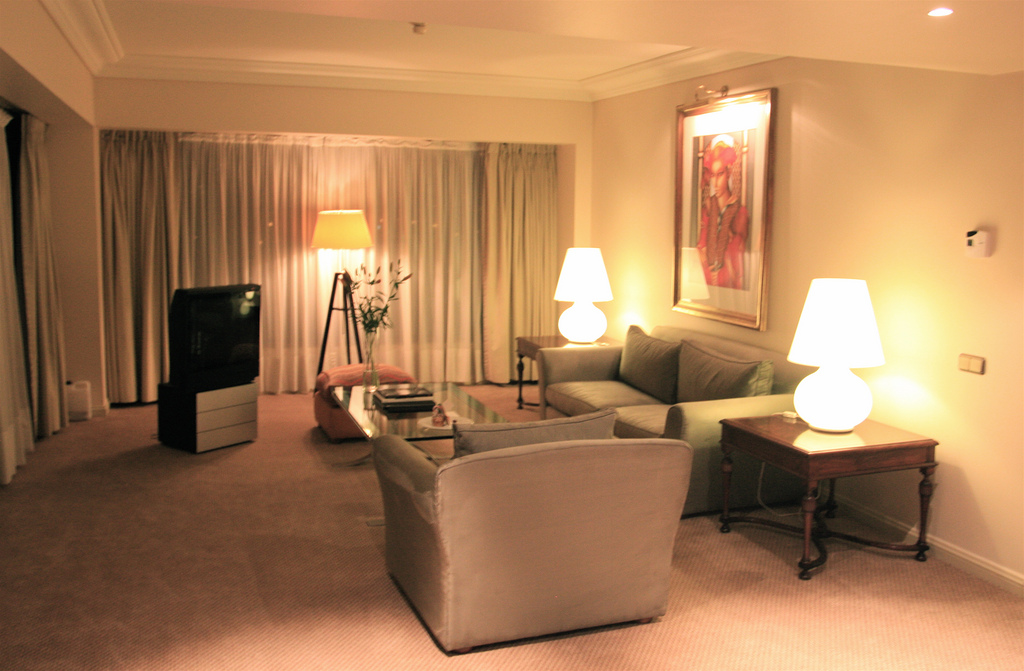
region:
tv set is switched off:
[173, 283, 268, 398]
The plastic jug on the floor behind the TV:
[54, 369, 100, 430]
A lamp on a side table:
[770, 246, 951, 597]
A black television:
[134, 234, 311, 421]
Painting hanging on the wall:
[622, 82, 820, 349]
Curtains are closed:
[78, 107, 610, 415]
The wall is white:
[809, 131, 912, 255]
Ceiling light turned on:
[916, 2, 978, 42]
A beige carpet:
[93, 507, 297, 627]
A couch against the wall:
[538, 322, 803, 511]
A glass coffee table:
[318, 359, 511, 458]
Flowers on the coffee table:
[302, 219, 428, 423]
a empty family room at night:
[78, 62, 946, 632]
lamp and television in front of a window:
[98, 122, 368, 449]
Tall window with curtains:
[280, 137, 553, 381]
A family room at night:
[67, 74, 962, 634]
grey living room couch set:
[370, 320, 800, 650]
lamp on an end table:
[721, 242, 946, 560]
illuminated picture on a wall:
[645, 30, 772, 341]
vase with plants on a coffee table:
[313, 251, 427, 444]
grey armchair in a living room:
[367, 415, 691, 657]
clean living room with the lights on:
[123, 73, 934, 633]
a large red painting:
[680, 95, 769, 352]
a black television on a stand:
[173, 280, 263, 402]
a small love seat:
[401, 431, 711, 643]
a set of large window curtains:
[122, 146, 569, 390]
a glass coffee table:
[347, 374, 507, 442]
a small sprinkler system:
[392, 14, 431, 41]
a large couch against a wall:
[537, 324, 781, 489]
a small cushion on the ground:
[315, 368, 417, 442]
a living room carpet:
[103, 472, 357, 640]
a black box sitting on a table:
[372, 381, 442, 413]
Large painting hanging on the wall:
[653, 92, 797, 347]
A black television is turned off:
[140, 275, 288, 425]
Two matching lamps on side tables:
[499, 221, 916, 457]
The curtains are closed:
[103, 84, 590, 417]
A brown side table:
[714, 377, 946, 572]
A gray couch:
[542, 308, 791, 514]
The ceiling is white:
[162, 4, 347, 80]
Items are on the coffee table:
[324, 353, 481, 485]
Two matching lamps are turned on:
[503, 219, 916, 470]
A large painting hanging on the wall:
[641, 70, 804, 370]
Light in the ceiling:
[901, 4, 984, 52]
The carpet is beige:
[98, 494, 317, 602]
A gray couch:
[357, 388, 717, 655]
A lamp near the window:
[288, 181, 408, 387]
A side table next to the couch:
[688, 330, 966, 612]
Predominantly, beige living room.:
[10, 82, 748, 661]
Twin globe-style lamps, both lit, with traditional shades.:
[555, 258, 889, 459]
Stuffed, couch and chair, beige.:
[342, 362, 870, 653]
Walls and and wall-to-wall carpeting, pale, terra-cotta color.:
[368, 92, 1002, 661]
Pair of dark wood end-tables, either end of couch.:
[519, 333, 849, 621]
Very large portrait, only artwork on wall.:
[666, 97, 807, 370]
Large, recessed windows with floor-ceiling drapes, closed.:
[24, 107, 673, 468]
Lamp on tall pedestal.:
[307, 198, 388, 401]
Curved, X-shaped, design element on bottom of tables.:
[490, 300, 940, 634]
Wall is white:
[817, 127, 941, 234]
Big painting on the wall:
[632, 82, 805, 360]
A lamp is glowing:
[766, 256, 894, 445]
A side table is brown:
[737, 385, 945, 550]